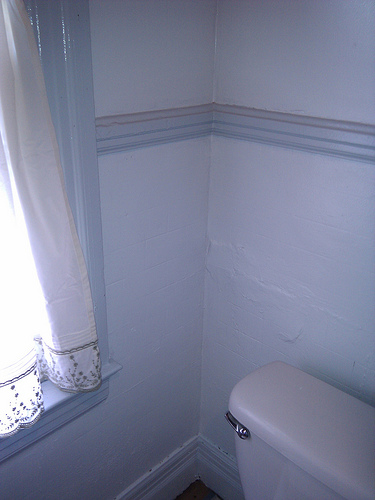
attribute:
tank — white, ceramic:
[224, 363, 374, 499]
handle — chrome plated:
[225, 413, 252, 440]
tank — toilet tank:
[227, 355, 343, 499]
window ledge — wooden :
[0, 357, 125, 460]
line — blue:
[216, 118, 370, 156]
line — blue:
[94, 120, 211, 143]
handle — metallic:
[220, 410, 256, 440]